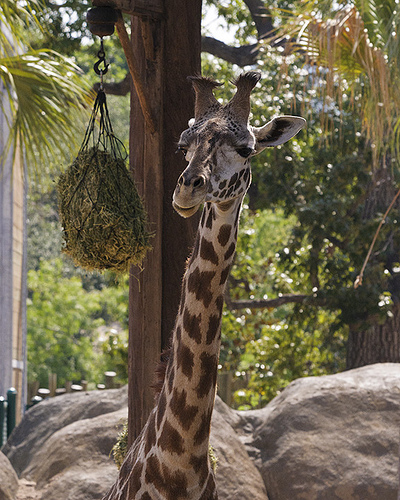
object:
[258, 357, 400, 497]
rocks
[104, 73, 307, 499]
giraffe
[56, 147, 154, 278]
hay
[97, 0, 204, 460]
pole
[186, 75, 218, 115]
horn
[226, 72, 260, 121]
horn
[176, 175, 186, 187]
nostril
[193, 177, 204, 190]
nostril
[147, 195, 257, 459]
neck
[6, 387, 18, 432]
fence post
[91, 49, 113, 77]
hook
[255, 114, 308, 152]
ear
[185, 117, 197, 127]
ear